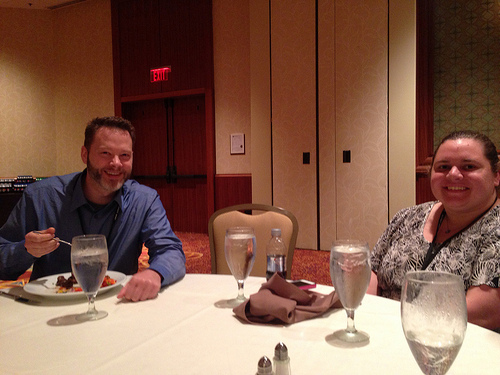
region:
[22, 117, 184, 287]
man wearing a blue shirt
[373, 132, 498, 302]
woman wearing a black and white shirt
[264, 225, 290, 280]
plastic soda bottle on the table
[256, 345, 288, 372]
salt and pepper shaker on the table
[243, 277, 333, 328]
brown cloth napkin on top of the table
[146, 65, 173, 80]
lighted exit sign above the doors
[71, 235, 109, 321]
water glass in front of the man's plate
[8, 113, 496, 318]
man and a woman sitting at a round table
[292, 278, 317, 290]
phone sitting on a table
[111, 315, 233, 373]
white tablecloth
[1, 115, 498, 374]
two people sitting at the table inside a restaurant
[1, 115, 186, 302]
a man sitting at the table inside a restaurant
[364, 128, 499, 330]
a woman sitting at the dining table in a restaurant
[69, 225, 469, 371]
four glasses on the dining table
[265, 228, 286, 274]
a beverage plastic bottle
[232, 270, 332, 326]
a brown cloth napkin on the table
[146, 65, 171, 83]
an exit sign above the doors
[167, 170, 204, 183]
a black handle bar on the right door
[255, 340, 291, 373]
salt and pepper glass shakers on the table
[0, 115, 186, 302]
a man in a blue shirt eating dinner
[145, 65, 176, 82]
a neon exit sign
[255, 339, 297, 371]
salt and pepper shakers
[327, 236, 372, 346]
a wine glass of water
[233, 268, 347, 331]
a brown cloth napkin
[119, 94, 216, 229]
double doors to exit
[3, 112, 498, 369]
two people at a table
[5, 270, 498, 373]
a white table cloth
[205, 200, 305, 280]
an empty chair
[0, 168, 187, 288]
long sleeve blue shirt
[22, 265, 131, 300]
a plate of food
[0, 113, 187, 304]
a man sitting at a table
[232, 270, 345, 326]
a crumpled brown napkin on a table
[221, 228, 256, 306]
a full glass of water on a table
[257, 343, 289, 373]
tip of a salt and pepper shaker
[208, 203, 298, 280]
the seat of a chair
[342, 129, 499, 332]
a woman sitting at a table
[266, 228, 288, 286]
a bottle on a table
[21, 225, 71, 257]
man holding a utensil in his hand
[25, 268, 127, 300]
a white plate with meat and veggies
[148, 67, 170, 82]
a red exit sign above a door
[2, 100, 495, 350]
Two people sitting at a table.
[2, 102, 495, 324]
A man and woman sitting at a table.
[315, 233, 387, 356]
A tall glass of water.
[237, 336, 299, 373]
Salt and pepper shakers on a table.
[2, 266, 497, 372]
White tablecloth on a round table.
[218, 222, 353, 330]
Brown napkin beside a glass of water.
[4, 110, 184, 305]
Man eating a meal.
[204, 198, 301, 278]
Empty chair at a table.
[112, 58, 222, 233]
Exit sign above a doorway.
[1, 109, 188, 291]
Man wearing a blue dress shirt.